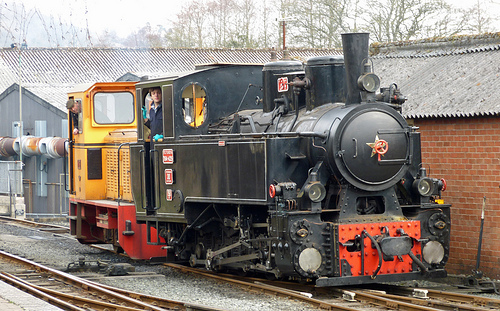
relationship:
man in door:
[134, 85, 164, 212] [136, 85, 157, 219]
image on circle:
[366, 134, 389, 161] [331, 105, 416, 189]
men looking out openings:
[61, 87, 165, 137] [134, 86, 170, 142]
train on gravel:
[53, 25, 461, 295] [0, 215, 499, 311]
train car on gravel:
[65, 75, 179, 260] [0, 215, 499, 311]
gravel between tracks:
[1, 215, 336, 309] [3, 246, 212, 309]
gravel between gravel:
[1, 215, 336, 309] [0, 215, 499, 311]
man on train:
[141, 86, 164, 162] [53, 25, 461, 295]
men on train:
[65, 98, 80, 135] [53, 25, 461, 295]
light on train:
[278, 236, 335, 296] [11, 43, 421, 292]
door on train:
[142, 86, 163, 216] [53, 25, 461, 295]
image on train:
[367, 136, 395, 161] [53, 25, 461, 295]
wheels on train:
[183, 242, 224, 272] [42, 44, 452, 286]